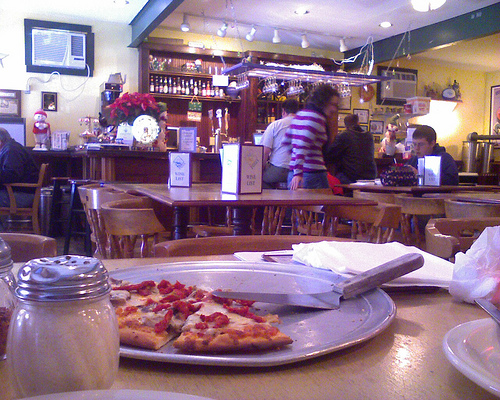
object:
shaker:
[7, 254, 122, 394]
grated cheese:
[7, 303, 121, 392]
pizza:
[110, 278, 290, 364]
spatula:
[210, 252, 426, 311]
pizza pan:
[105, 256, 395, 367]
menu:
[219, 140, 266, 195]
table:
[132, 182, 381, 215]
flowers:
[110, 94, 131, 120]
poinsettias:
[126, 93, 156, 104]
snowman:
[32, 106, 52, 152]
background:
[0, 12, 270, 139]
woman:
[286, 81, 339, 195]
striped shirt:
[280, 110, 327, 176]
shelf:
[145, 89, 241, 105]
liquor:
[150, 75, 155, 92]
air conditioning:
[31, 27, 83, 69]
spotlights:
[335, 36, 357, 53]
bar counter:
[80, 126, 205, 165]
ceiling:
[8, 0, 496, 22]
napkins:
[290, 238, 464, 289]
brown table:
[5, 251, 476, 399]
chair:
[99, 198, 162, 257]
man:
[330, 112, 377, 186]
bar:
[68, 142, 417, 187]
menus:
[167, 150, 193, 188]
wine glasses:
[345, 82, 352, 97]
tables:
[342, 182, 500, 197]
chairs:
[77, 185, 129, 252]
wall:
[5, 7, 129, 101]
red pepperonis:
[169, 292, 181, 299]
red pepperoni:
[214, 315, 227, 326]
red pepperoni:
[232, 306, 250, 313]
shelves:
[141, 40, 242, 151]